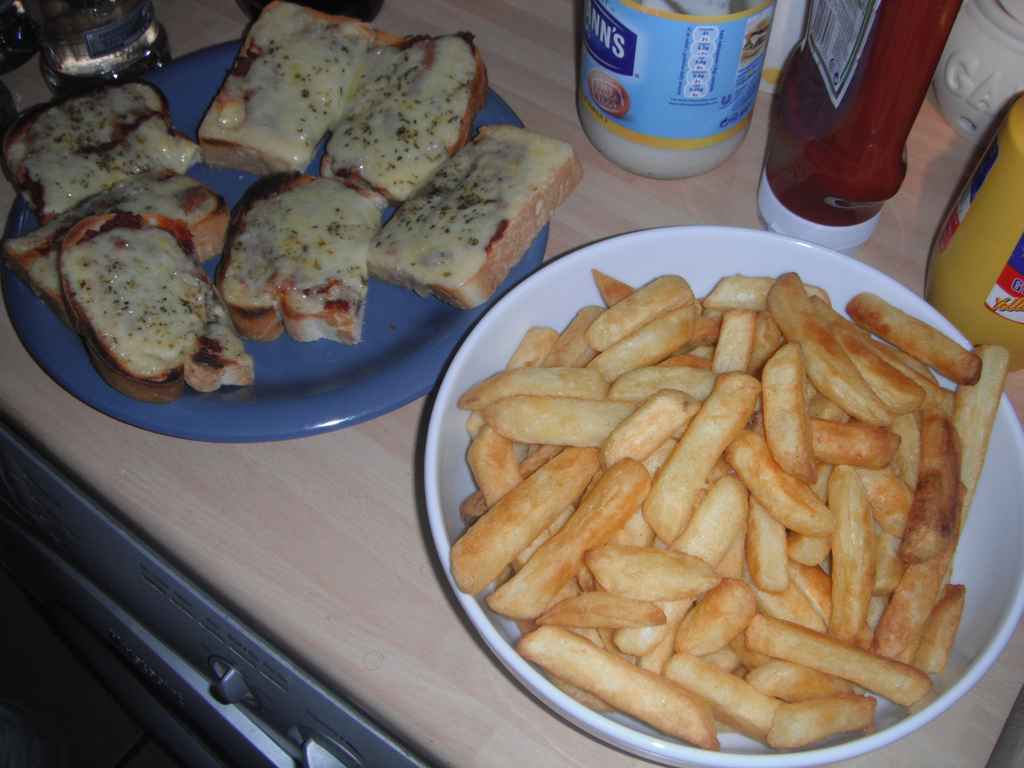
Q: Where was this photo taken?
A: On a countertop.